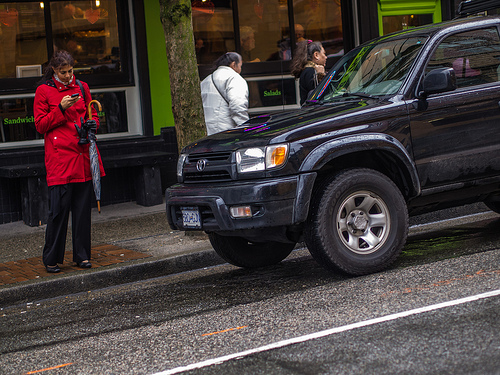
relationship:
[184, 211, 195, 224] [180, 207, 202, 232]
letter on sign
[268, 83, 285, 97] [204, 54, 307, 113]
letter on sign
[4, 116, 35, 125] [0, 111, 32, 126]
letters on sign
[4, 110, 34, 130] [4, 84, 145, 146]
letters on sign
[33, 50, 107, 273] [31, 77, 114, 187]
people wears jacket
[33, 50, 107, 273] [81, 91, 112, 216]
people holds umbrella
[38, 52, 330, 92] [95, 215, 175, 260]
people on sidewalk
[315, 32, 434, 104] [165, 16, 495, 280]
windshield of car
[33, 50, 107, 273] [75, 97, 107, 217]
people holding umbrella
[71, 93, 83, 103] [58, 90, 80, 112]
phone in hand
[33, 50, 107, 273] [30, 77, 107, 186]
people in coat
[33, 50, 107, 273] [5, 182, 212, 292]
people on sidewalk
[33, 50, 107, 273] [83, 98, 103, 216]
people carrying umbrella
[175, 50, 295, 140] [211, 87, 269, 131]
woman with purse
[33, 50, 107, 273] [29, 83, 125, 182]
people in shirt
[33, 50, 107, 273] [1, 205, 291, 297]
people in sidewalk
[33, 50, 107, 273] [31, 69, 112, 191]
people wearing coat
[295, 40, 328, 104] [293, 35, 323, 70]
woman with hair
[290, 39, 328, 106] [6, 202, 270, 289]
woman walking down sidewalk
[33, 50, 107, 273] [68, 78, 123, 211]
people holding an umbrella